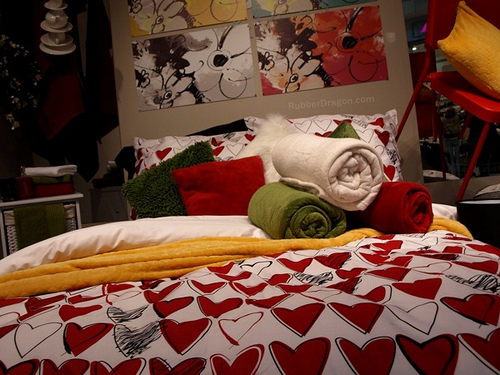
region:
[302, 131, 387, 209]
a white rolled up towel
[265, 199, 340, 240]
a green rolled up towel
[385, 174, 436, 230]
a red rolled up towel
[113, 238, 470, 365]
a bed spread with a heart design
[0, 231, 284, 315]
a yellow throw blanket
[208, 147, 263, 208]
a red pillow on a bed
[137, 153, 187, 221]
a green pillow on a bed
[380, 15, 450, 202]
a red chair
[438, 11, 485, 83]
a yellow pillow on a red chair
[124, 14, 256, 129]
a picture on a wall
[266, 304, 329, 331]
red heart on spread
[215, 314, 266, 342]
white heart on spread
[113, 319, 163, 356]
black and white heart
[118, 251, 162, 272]
gold blanket on bed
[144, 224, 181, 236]
white sheet on bed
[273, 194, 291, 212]
green blanket on bed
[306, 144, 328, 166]
white blanket on bed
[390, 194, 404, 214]
red blanket on bed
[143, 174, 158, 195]
green pillow on bed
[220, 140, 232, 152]
heart pillow on bed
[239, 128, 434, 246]
Towels are red, white and green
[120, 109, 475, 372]
Folded towels sitting on a bed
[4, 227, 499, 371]
Comforter has hearts on it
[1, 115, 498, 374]
The bed is made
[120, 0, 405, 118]
Pictures of flowers are on the wall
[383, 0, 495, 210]
Red chair with a yellow pillow on it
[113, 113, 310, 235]
The pillows are green, red and white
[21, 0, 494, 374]
Chair is located funny in proportion to the bed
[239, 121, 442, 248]
White towel is on top of the green and red ones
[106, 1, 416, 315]
There are 4 pictures hanging above the bed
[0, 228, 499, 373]
White comforter with red heart pattern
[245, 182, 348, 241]
Olive green fleece blanket rolled up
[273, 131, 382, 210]
Off white blanket rolled up on bed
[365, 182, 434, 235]
Dark red blanket in a roll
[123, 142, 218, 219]
Plush dark green throw pillow on bed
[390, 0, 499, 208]
Red metal folding chair with yellow pillow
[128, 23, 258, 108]
Black and white painting of flowers on wall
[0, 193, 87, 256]
Books in white book shelf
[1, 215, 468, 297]
Mustard yellow blanket folded back on bed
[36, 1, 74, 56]
White ridged light fixture in bedroom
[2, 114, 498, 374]
this is a bed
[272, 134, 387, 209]
this is a white blanket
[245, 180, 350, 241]
this is a green blanket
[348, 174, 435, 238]
this is a red blanket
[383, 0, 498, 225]
this is a red piece of metal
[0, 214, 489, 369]
this is the red and white comforter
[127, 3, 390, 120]
these are wall paintings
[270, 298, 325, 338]
this is a red heart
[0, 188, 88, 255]
this is a desk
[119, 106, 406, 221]
these are some pillows